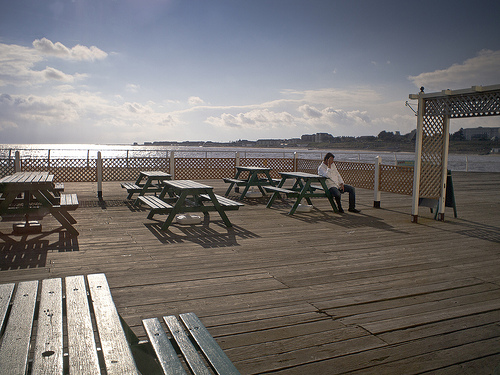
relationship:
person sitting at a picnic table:
[317, 151, 362, 217] [265, 168, 345, 218]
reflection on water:
[23, 142, 150, 162] [1, 141, 499, 169]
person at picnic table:
[317, 151, 362, 217] [265, 168, 345, 218]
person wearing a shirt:
[317, 151, 362, 217] [318, 162, 351, 190]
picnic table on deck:
[265, 168, 345, 218] [1, 172, 496, 372]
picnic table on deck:
[220, 160, 283, 207] [1, 172, 496, 372]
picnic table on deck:
[134, 176, 247, 238] [1, 172, 496, 372]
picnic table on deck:
[120, 168, 185, 212] [1, 172, 496, 372]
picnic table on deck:
[4, 171, 85, 234] [1, 172, 496, 372]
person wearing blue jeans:
[317, 151, 362, 217] [329, 184, 356, 214]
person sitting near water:
[317, 151, 362, 217] [1, 141, 499, 169]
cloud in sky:
[1, 37, 121, 84] [2, 2, 497, 146]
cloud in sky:
[156, 113, 182, 130] [2, 2, 497, 146]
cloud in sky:
[203, 105, 306, 134] [2, 2, 497, 146]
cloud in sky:
[297, 103, 386, 131] [2, 2, 497, 146]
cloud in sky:
[410, 46, 499, 88] [2, 2, 497, 146]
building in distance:
[459, 126, 497, 142] [133, 114, 500, 160]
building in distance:
[257, 135, 293, 147] [133, 114, 500, 160]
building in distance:
[303, 130, 328, 144] [133, 114, 500, 160]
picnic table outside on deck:
[265, 168, 345, 218] [1, 172, 496, 372]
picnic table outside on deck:
[220, 160, 283, 207] [1, 172, 496, 372]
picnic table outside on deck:
[134, 176, 247, 238] [1, 172, 496, 372]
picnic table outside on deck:
[120, 168, 185, 212] [1, 172, 496, 372]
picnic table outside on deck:
[4, 171, 85, 234] [1, 172, 496, 372]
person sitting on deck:
[317, 151, 362, 217] [1, 172, 496, 372]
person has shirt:
[317, 151, 362, 217] [318, 162, 351, 190]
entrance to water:
[447, 117, 500, 232] [1, 141, 499, 169]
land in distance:
[134, 141, 498, 160] [133, 114, 500, 160]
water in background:
[1, 141, 499, 169] [1, 121, 491, 178]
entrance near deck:
[447, 117, 500, 232] [1, 172, 496, 372]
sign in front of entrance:
[424, 169, 459, 219] [447, 117, 500, 232]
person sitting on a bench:
[317, 151, 362, 217] [313, 182, 344, 195]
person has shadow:
[317, 151, 362, 217] [333, 208, 411, 240]